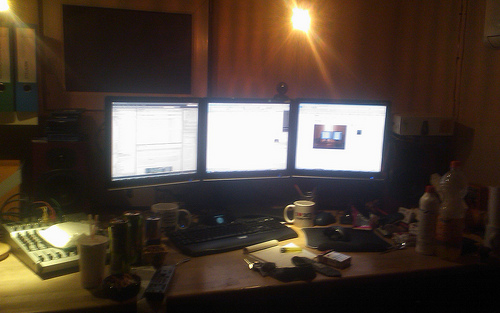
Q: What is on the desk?
A: Computer monitors.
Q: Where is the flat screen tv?
A: On the table.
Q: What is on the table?
A: Computer.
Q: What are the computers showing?
A: Internet pages.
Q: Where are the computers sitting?
A: On the table.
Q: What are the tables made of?
A: Wood.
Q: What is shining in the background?
A: Light.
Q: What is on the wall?
A: TV.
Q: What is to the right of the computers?
A: Bottles.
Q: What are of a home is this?
A: Home office.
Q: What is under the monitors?
A: Keyboard.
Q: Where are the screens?
A: On the desk.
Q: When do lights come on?
A: When it's dark.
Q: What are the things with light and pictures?
A: Monitors.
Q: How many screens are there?
A: Three.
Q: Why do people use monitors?
A: To see what's on the computer.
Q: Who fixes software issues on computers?
A: IT.